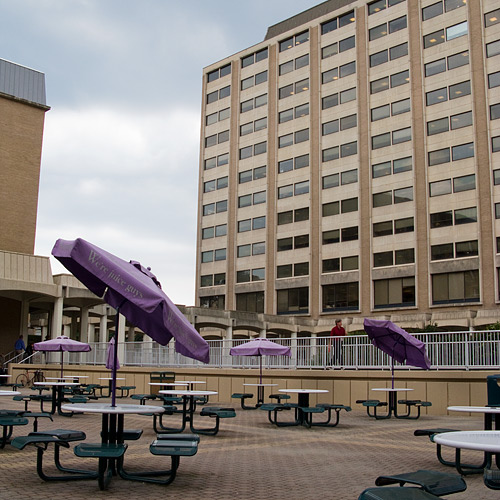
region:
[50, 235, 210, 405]
a purple patio umbrella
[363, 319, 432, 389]
a purple patio umbrella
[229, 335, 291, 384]
a purple patio umbrella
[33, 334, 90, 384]
a purple patio umbrella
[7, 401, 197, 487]
an outdoor dining table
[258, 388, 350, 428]
an outdoor dining table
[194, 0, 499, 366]
a large building with a lot of windows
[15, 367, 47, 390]
a bike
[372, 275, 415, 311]
a window on a building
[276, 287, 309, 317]
a window on a building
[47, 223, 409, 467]
outside patio with tables and chairs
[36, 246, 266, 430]
purple umbrella over table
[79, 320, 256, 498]
green seats attached to table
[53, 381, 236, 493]
table has white top and black pole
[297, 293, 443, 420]
man walking past patio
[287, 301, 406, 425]
man wearing red shirt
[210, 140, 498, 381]
building has big and small windows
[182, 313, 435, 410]
walkway has white fencing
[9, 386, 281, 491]
patio is made of bricks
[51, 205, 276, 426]
umbrella is tilted over table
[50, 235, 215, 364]
tilted purple umbrella with white writing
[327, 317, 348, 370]
walking man in a red shirt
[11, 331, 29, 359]
person in a blue shirt climbing a staircase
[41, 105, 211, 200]
puffy white cloud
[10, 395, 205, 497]
white and green picknick table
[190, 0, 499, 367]
11 story tan building with many glass windows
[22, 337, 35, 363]
person wearing black clothes climbing a staircase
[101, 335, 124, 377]
closed purple umbrella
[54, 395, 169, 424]
round white table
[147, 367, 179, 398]
black and brown garbage can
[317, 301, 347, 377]
man walking on walkway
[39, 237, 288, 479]
picnic tables at a restaurant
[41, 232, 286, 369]
umbrellas at outdoor dining tables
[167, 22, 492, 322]
high rise building with walkway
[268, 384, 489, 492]
outdoor dining seating without umbrellas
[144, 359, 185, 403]
garbage can for outdoor seating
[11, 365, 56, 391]
a bicycle set near a stairwell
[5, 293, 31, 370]
man walking up staircase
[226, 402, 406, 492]
brick layout for dining area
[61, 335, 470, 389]
walkway with guardrails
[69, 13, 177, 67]
this is the sky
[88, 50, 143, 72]
the sky is blue in color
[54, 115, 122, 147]
these are the clouds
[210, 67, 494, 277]
this is a building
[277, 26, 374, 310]
the building is a tall one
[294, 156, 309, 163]
this is a glass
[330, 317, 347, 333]
this is a man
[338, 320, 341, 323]
the man is light skinned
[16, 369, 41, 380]
this is a bicycle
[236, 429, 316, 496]
this is the floor